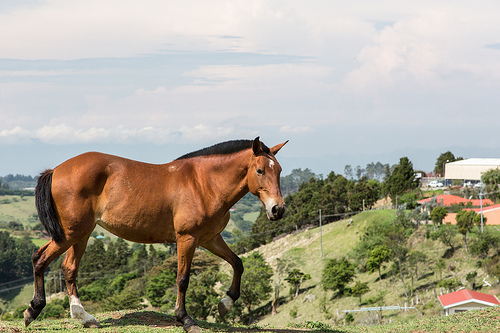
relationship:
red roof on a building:
[436, 287, 498, 308] [433, 287, 499, 317]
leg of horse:
[173, 230, 200, 330] [20, 138, 292, 331]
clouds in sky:
[370, 16, 481, 74] [3, 3, 497, 133]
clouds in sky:
[360, 20, 450, 81] [0, 1, 498, 181]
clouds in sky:
[2, 0, 499, 182] [0, 1, 498, 181]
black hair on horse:
[172, 137, 277, 159] [20, 138, 292, 331]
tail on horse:
[31, 165, 68, 251] [20, 138, 292, 331]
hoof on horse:
[217, 297, 237, 318] [20, 138, 292, 331]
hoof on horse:
[172, 316, 201, 331] [20, 138, 292, 331]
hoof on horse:
[65, 304, 100, 331] [20, 138, 292, 331]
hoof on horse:
[21, 307, 37, 329] [20, 138, 292, 331]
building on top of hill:
[439, 153, 499, 195] [276, 212, 388, 245]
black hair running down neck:
[172, 137, 277, 159] [210, 144, 250, 211]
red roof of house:
[436, 287, 498, 308] [435, 288, 499, 316]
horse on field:
[20, 138, 292, 331] [2, 304, 307, 329]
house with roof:
[429, 286, 498, 316] [436, 277, 498, 319]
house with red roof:
[412, 190, 494, 217] [413, 188, 492, 210]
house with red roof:
[435, 288, 499, 316] [432, 287, 498, 312]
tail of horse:
[31, 165, 68, 251] [20, 138, 292, 331]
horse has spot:
[20, 138, 292, 331] [266, 157, 276, 172]